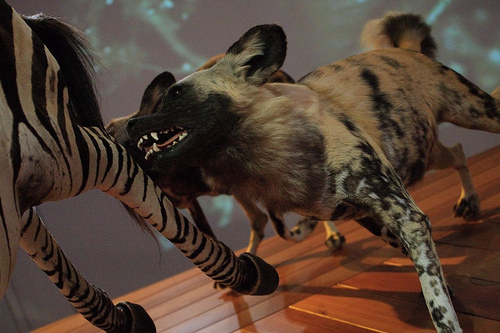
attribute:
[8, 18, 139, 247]
zebra — running, white, back, black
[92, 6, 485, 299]
light — on, predator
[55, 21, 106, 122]
animal — tail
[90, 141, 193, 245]
leg — zebra, lifted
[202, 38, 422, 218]
hyena — chasing, going, attacking, attack mode, yellow, short, belly, running, bit, after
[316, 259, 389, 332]
table — wooden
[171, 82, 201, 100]
eye — small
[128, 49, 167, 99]
muzzle — black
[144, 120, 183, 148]
tooth — pointed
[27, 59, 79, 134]
stripe — black